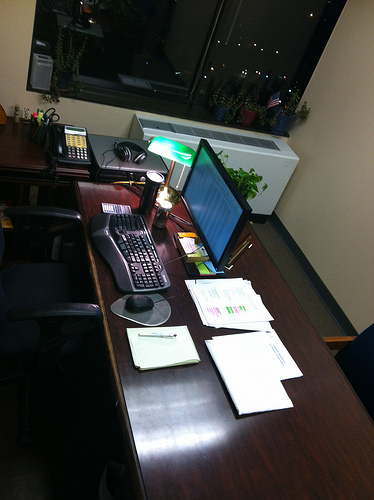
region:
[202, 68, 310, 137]
a row of plants in the windowsill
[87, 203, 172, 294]
a black keyboard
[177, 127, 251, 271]
a flat screen monitor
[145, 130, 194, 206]
a small green desk lamp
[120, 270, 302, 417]
three stacks of paper on the desk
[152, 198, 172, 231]
a can of soda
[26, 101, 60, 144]
a cup with pens, highlighters, and scissors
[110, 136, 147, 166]
a pair of headphones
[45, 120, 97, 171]
a telephone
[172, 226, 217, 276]
a tray under the monitor with business cards and sticky notes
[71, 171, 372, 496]
the desk is brown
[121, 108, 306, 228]
the air conditioning unit is white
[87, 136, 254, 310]
a computer is sitting on the desk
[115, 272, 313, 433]
piles of papers are on the desk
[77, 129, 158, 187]
the headphones are black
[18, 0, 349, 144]
the window is big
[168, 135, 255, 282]
the computer screen is on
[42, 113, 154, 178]
a telephone is beside the headphones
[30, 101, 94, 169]
beside the phone is a pair of scissors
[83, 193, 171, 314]
beside the keyboard is a calculator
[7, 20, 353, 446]
A large office.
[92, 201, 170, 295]
A keyboard.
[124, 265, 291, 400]
A pile of papers on the desk.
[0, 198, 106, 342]
A leather computer chair.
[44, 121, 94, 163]
A telephone.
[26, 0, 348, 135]
A large window with a view.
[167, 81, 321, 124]
Potted plants on the windowsill.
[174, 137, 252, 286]
A computer monitor with a spreadsheet on it.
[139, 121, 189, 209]
A lamp that is turned on.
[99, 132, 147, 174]
A pair of headphones.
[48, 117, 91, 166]
A black digital telephone.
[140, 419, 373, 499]
A brown wooden table.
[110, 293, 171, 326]
A black computer mouse on a gray mouse pad.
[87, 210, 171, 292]
A black computer keyboard.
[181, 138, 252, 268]
A computer monitor with a blue screen.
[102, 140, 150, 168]
Black headphones on the briefcase.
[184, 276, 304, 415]
A pile of papers on desk.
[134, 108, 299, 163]
The top of the radiator.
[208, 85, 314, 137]
Three plants and a flag on windowsill.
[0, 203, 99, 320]
The arms of the computer chair.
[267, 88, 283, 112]
The American flag on the windowsill.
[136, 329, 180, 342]
The pen on top of the pile of papers on the desk.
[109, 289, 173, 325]
The gray mouse pad beneath the mouse on the desk.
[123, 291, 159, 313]
The black mouse on top of the mouse pad.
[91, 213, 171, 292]
The black keyboard on the desk.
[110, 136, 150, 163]
The earphones to the left of the desk.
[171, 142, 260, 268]
The computer screen monitor on the desk.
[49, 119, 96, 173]
The black telephone on the desk closest to the window.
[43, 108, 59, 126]
The scissors in the cup next to the telephone.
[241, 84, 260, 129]
The red plant pot on the windowsill.